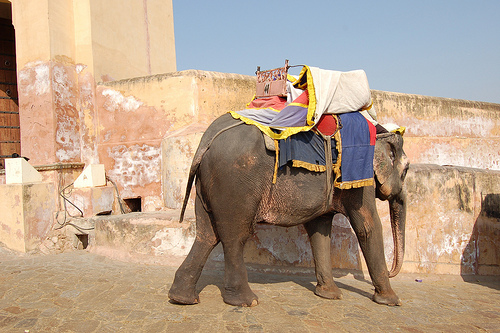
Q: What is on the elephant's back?
A: A seat.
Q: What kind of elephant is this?
A: An adult.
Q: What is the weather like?
A: Sunny and warm.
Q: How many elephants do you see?
A: 1 elephant.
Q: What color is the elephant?
A: The elephant is discolored.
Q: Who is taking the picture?
A: A photographer.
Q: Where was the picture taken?
A: On the street.